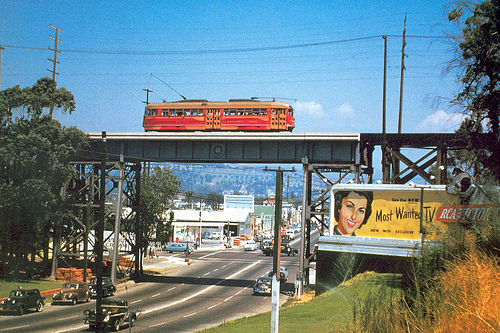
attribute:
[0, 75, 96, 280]
trees — on left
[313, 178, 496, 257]
billboard — for RCA Victor TV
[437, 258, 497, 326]
grass — tall, brown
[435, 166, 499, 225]
advertisement — RCA 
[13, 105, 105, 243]
green trees — large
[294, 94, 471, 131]
clouds — white, puffy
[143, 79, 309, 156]
trains — public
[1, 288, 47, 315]
car — old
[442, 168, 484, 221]
dog — black and white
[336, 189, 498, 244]
billboard — advertisement, television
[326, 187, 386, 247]
woman — smiling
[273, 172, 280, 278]
telephone pole — wooden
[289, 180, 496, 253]
billboard — yellow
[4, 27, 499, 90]
wires — electric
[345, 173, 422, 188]
lights — three 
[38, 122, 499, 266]
railway — overhanging, public , train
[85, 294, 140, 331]
car — old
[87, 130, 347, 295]
beams — iron 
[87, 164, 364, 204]
city —  countryside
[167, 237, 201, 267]
car — blue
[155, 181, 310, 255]
shops — public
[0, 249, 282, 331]
lines — white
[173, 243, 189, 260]
car — blue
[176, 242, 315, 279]
intersection — four way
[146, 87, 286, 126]
car — trolley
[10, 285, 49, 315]
car — black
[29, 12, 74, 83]
pole — telephone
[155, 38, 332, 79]
lines — telephone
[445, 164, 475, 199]
head — RCA, pupies